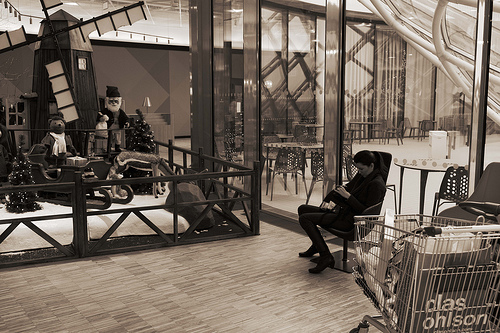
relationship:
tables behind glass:
[237, 122, 456, 185] [264, 1, 477, 162]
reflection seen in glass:
[225, 16, 482, 93] [264, 1, 477, 162]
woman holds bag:
[297, 166, 383, 260] [308, 174, 360, 220]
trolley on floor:
[344, 198, 490, 325] [27, 269, 297, 331]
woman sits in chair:
[297, 166, 383, 260] [369, 143, 399, 242]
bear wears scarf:
[41, 120, 79, 175] [53, 135, 64, 153]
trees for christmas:
[13, 90, 187, 205] [119, 98, 159, 154]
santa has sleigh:
[95, 80, 131, 152] [19, 143, 135, 215]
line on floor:
[180, 247, 278, 280] [27, 269, 297, 331]